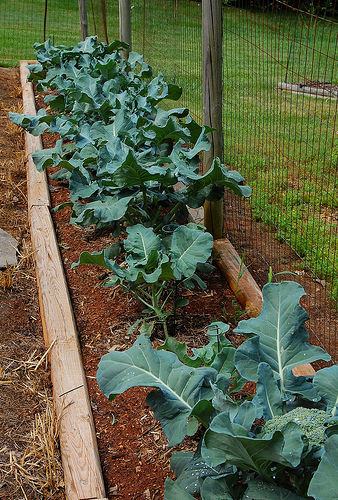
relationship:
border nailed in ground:
[45, 423, 87, 488] [0, 65, 36, 498]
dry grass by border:
[0, 347, 74, 499] [17, 50, 106, 488]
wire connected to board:
[279, 185, 329, 247] [197, 1, 229, 239]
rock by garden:
[1, 225, 19, 273] [36, 52, 300, 431]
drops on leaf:
[120, 369, 134, 382] [233, 277, 328, 399]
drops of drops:
[185, 462, 210, 493] [120, 369, 134, 382]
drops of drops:
[309, 394, 318, 402] [120, 369, 134, 382]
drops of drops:
[287, 443, 297, 458] [120, 369, 134, 382]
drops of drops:
[253, 477, 287, 495] [120, 369, 134, 382]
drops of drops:
[119, 366, 142, 385] [120, 369, 134, 382]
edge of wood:
[91, 432, 110, 496] [39, 309, 106, 498]